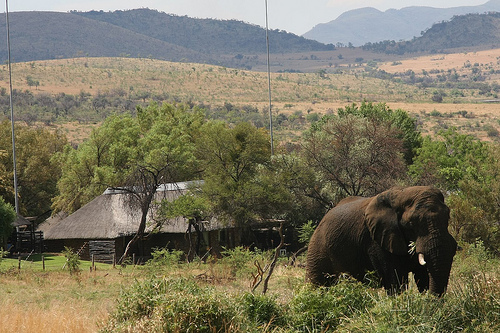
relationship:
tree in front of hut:
[54, 107, 215, 267] [23, 175, 296, 265]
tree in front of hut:
[195, 109, 282, 252] [23, 175, 296, 265]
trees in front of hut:
[251, 155, 330, 249] [23, 175, 296, 265]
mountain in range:
[367, 12, 498, 52] [3, 2, 499, 65]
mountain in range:
[298, 0, 498, 48] [3, 2, 499, 65]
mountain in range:
[72, 0, 334, 54] [3, 2, 499, 65]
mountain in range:
[0, 10, 215, 64] [3, 2, 499, 65]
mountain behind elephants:
[399, 12, 498, 52] [295, 175, 472, 302]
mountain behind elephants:
[298, 0, 498, 48] [295, 175, 472, 302]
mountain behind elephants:
[67, 8, 334, 54] [295, 175, 472, 302]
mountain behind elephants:
[0, 10, 256, 67] [295, 175, 472, 302]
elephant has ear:
[305, 185, 457, 297] [364, 181, 404, 264]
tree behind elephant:
[54, 107, 215, 267] [321, 195, 450, 300]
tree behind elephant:
[195, 109, 282, 252] [321, 195, 450, 300]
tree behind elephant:
[253, 152, 334, 252] [321, 195, 450, 300]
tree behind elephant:
[305, 104, 425, 198] [321, 195, 450, 300]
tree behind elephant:
[305, 104, 422, 164] [321, 195, 450, 300]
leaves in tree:
[134, 120, 189, 161] [48, 110, 201, 269]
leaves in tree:
[134, 120, 189, 161] [172, 119, 275, 259]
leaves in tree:
[134, 120, 189, 161] [240, 151, 344, 249]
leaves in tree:
[439, 177, 498, 250] [443, 139, 499, 278]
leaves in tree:
[183, 115, 278, 198] [1, 123, 71, 218]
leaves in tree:
[401, 128, 498, 193] [280, 113, 410, 214]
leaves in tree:
[135, 105, 219, 181] [48, 110, 201, 269]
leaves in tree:
[76, 155, 96, 168] [405, 125, 499, 200]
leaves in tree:
[305, 113, 403, 177] [305, 104, 425, 198]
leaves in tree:
[305, 113, 403, 177] [255, 154, 326, 253]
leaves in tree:
[305, 113, 403, 177] [410, 157, 447, 191]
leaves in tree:
[305, 113, 403, 177] [444, 178, 499, 256]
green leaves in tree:
[168, 121, 242, 163] [50, 110, 195, 260]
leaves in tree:
[325, 101, 422, 161] [329, 102, 421, 193]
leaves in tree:
[265, 154, 329, 193] [255, 145, 322, 253]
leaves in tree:
[95, 113, 146, 175] [50, 110, 195, 260]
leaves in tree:
[33, 153, 45, 167] [2, 129, 63, 257]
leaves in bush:
[163, 295, 197, 316] [158, 291, 233, 331]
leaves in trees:
[76, 129, 150, 189] [41, 88, 279, 235]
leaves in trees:
[321, 119, 403, 167] [282, 102, 429, 197]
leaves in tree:
[318, 110, 399, 185] [292, 116, 406, 221]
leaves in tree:
[213, 138, 263, 212] [199, 122, 277, 244]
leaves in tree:
[264, 163, 317, 225] [246, 152, 332, 240]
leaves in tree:
[5, 125, 75, 202] [0, 124, 78, 220]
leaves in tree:
[314, 147, 376, 162] [304, 115, 407, 211]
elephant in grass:
[305, 185, 457, 297] [1, 237, 498, 330]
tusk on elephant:
[412, 245, 433, 269] [291, 180, 460, 307]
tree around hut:
[54, 107, 215, 267] [34, 179, 285, 265]